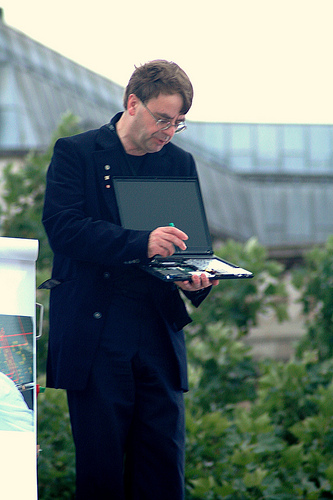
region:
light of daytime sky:
[14, 9, 322, 119]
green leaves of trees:
[189, 240, 330, 498]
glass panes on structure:
[6, 31, 328, 244]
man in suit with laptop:
[43, 58, 252, 498]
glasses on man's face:
[141, 103, 187, 132]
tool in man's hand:
[149, 221, 189, 259]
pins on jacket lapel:
[95, 120, 126, 207]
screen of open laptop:
[116, 180, 205, 244]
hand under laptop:
[151, 256, 249, 281]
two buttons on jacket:
[92, 268, 111, 319]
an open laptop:
[90, 150, 291, 350]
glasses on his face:
[135, 98, 213, 146]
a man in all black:
[24, 72, 230, 498]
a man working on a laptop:
[50, 77, 233, 498]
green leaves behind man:
[4, 143, 329, 485]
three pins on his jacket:
[95, 159, 115, 196]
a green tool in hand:
[166, 218, 199, 269]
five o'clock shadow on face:
[125, 109, 178, 164]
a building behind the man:
[8, 25, 332, 236]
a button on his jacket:
[85, 305, 112, 324]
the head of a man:
[115, 55, 205, 161]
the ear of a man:
[115, 84, 147, 124]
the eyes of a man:
[142, 112, 197, 131]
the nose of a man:
[152, 119, 183, 154]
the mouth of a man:
[148, 129, 178, 163]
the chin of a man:
[134, 133, 173, 164]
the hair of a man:
[117, 45, 235, 127]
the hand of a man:
[139, 214, 195, 278]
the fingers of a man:
[137, 206, 189, 270]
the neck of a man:
[96, 111, 140, 175]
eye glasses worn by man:
[141, 101, 184, 137]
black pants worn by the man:
[60, 288, 195, 496]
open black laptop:
[111, 175, 253, 283]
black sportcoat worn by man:
[47, 129, 207, 387]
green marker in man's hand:
[168, 221, 182, 251]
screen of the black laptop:
[117, 179, 206, 251]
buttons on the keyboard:
[157, 253, 240, 278]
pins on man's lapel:
[102, 162, 113, 193]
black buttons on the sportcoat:
[107, 269, 119, 311]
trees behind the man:
[6, 124, 331, 497]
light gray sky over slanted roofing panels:
[0, 4, 330, 179]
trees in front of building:
[0, 121, 322, 494]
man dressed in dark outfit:
[41, 56, 210, 492]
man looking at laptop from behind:
[102, 167, 250, 286]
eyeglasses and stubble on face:
[123, 54, 189, 151]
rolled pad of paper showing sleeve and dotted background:
[0, 226, 39, 493]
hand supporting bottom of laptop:
[145, 251, 249, 288]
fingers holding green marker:
[146, 218, 184, 255]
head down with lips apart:
[122, 55, 193, 154]